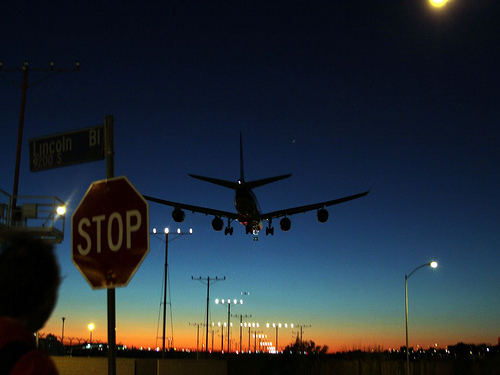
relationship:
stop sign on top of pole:
[74, 178, 157, 284] [86, 277, 127, 374]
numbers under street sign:
[21, 153, 57, 176] [36, 130, 115, 174]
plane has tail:
[126, 125, 385, 236] [195, 143, 282, 196]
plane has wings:
[126, 125, 385, 236] [147, 185, 391, 208]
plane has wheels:
[126, 125, 385, 236] [213, 217, 290, 252]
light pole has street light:
[392, 270, 423, 354] [422, 257, 439, 270]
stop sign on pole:
[74, 178, 157, 284] [86, 277, 127, 374]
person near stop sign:
[5, 240, 76, 375] [74, 178, 157, 284]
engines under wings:
[170, 204, 328, 231] [147, 185, 391, 208]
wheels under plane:
[213, 217, 290, 252] [126, 125, 385, 236]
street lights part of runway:
[146, 223, 296, 360] [204, 326, 351, 363]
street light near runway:
[388, 249, 437, 355] [204, 326, 351, 363]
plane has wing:
[126, 125, 385, 236] [260, 189, 367, 223]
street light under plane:
[388, 249, 437, 355] [126, 125, 385, 236]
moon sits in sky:
[423, 1, 454, 18] [87, 16, 419, 124]